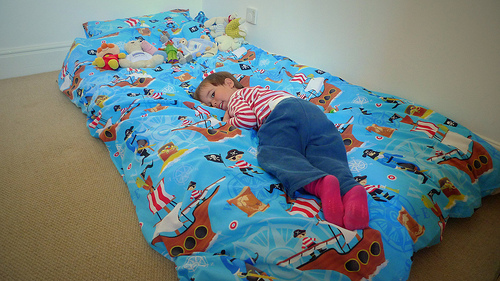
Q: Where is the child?
A: Lying on the bed.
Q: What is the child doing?
A: Resting.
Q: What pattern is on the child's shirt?
A: Stripes.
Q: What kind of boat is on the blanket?
A: Pirate Ship.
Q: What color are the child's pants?
A: Blue.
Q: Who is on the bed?
A: A child.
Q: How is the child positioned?
A: Prone.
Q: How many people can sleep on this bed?
A: One.